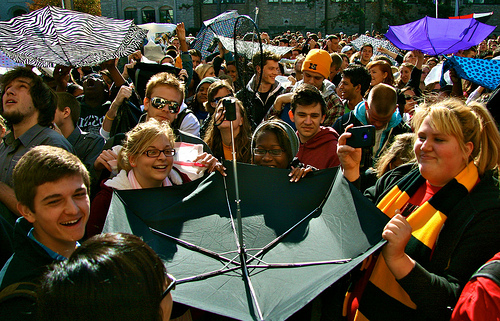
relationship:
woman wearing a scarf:
[370, 105, 499, 301] [372, 154, 492, 304]